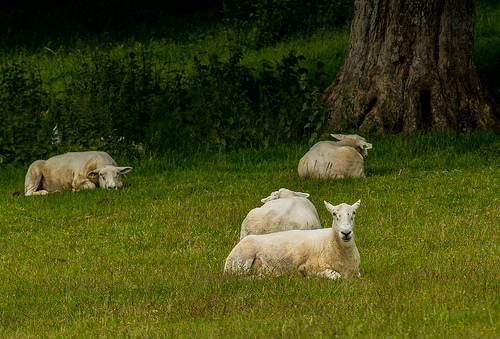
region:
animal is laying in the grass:
[21, 122, 413, 314]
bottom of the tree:
[203, 21, 496, 122]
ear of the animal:
[319, 199, 376, 212]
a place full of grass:
[28, 238, 167, 317]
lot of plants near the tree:
[69, 39, 381, 117]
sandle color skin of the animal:
[232, 223, 339, 276]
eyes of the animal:
[326, 207, 358, 218]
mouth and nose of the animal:
[106, 181, 118, 195]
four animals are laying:
[11, 103, 388, 290]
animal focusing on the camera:
[318, 192, 370, 243]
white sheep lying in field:
[225, 193, 372, 285]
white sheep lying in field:
[231, 185, 315, 226]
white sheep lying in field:
[290, 119, 365, 189]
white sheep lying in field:
[27, 143, 118, 200]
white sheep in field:
[20, 149, 137, 209]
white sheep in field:
[298, 128, 372, 173]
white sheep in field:
[231, 182, 305, 230]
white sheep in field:
[234, 198, 364, 283]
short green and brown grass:
[38, 233, 90, 273]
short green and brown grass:
[381, 272, 431, 309]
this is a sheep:
[15, 145, 145, 226]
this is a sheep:
[209, 198, 386, 295]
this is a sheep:
[231, 168, 333, 245]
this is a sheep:
[297, 83, 381, 188]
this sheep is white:
[20, 137, 134, 212]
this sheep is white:
[201, 193, 388, 295]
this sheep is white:
[236, 167, 331, 242]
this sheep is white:
[300, 112, 400, 187]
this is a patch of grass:
[98, 230, 188, 304]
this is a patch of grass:
[33, 254, 98, 315]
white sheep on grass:
[28, 133, 123, 205]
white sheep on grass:
[207, 185, 367, 280]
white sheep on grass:
[218, 182, 315, 239]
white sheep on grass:
[287, 118, 359, 193]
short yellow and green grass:
[31, 228, 102, 268]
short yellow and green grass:
[71, 208, 126, 252]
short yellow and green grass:
[22, 233, 80, 274]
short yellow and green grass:
[150, 236, 190, 297]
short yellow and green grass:
[384, 259, 424, 296]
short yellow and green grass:
[420, 182, 460, 233]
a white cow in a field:
[222, 199, 366, 281]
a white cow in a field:
[19, 144, 132, 193]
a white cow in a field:
[297, 133, 372, 180]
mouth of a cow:
[339, 228, 351, 241]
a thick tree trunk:
[332, 0, 494, 138]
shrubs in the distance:
[0, 50, 323, 160]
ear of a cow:
[115, 162, 131, 176]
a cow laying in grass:
[23, 150, 127, 200]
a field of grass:
[2, 145, 498, 337]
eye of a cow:
[113, 168, 118, 176]